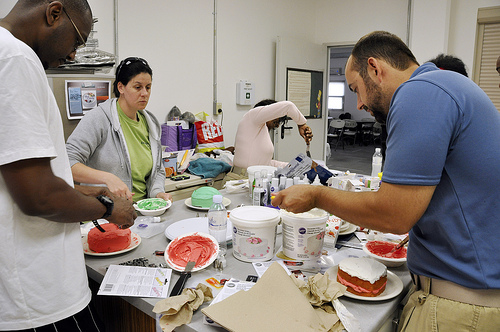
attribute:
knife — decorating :
[301, 140, 321, 158]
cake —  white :
[337, 254, 395, 300]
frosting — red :
[339, 224, 394, 246]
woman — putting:
[231, 91, 323, 174]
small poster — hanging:
[64, 80, 114, 117]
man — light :
[270, 25, 497, 330]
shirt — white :
[4, 22, 158, 329]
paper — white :
[97, 262, 170, 296]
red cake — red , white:
[84, 208, 217, 271]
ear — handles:
[45, 0, 64, 25]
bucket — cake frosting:
[228, 204, 280, 264]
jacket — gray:
[78, 110, 127, 186]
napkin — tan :
[147, 279, 215, 330]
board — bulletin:
[41, 62, 114, 140]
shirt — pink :
[235, 96, 313, 176]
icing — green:
[189, 181, 215, 205]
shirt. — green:
[75, 98, 158, 205]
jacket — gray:
[71, 90, 166, 218]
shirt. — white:
[0, 28, 97, 318]